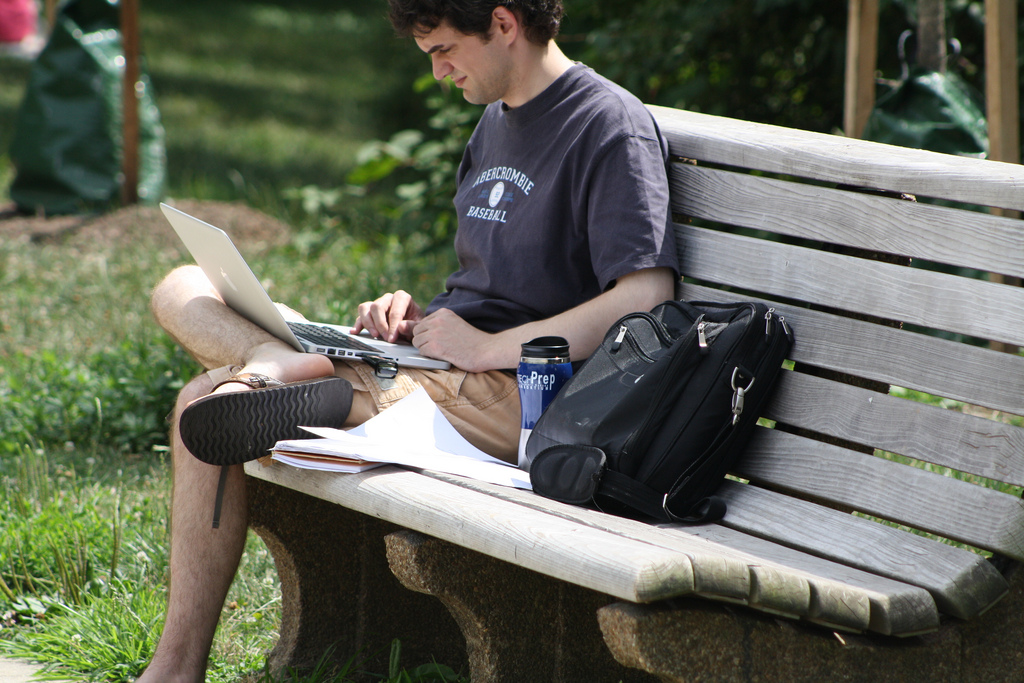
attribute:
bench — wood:
[355, 450, 714, 576]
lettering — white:
[511, 365, 568, 398]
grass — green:
[6, 229, 465, 677]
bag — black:
[530, 294, 790, 519]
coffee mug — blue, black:
[518, 330, 570, 467]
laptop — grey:
[155, 199, 458, 379]